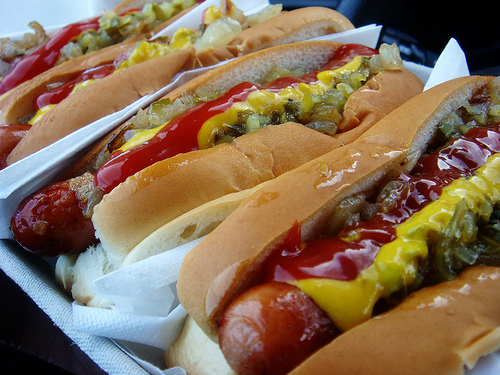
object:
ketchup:
[165, 121, 199, 152]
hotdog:
[9, 175, 102, 257]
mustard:
[291, 82, 318, 100]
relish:
[310, 105, 343, 122]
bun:
[93, 65, 425, 273]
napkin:
[71, 236, 208, 352]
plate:
[0, 243, 149, 375]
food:
[6, 44, 425, 272]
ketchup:
[303, 246, 353, 271]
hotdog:
[219, 281, 336, 375]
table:
[0, 268, 107, 375]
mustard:
[369, 256, 410, 294]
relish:
[432, 196, 468, 280]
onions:
[132, 109, 150, 127]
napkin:
[0, 25, 382, 240]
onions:
[194, 17, 242, 50]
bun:
[59, 40, 341, 180]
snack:
[2, 2, 203, 91]